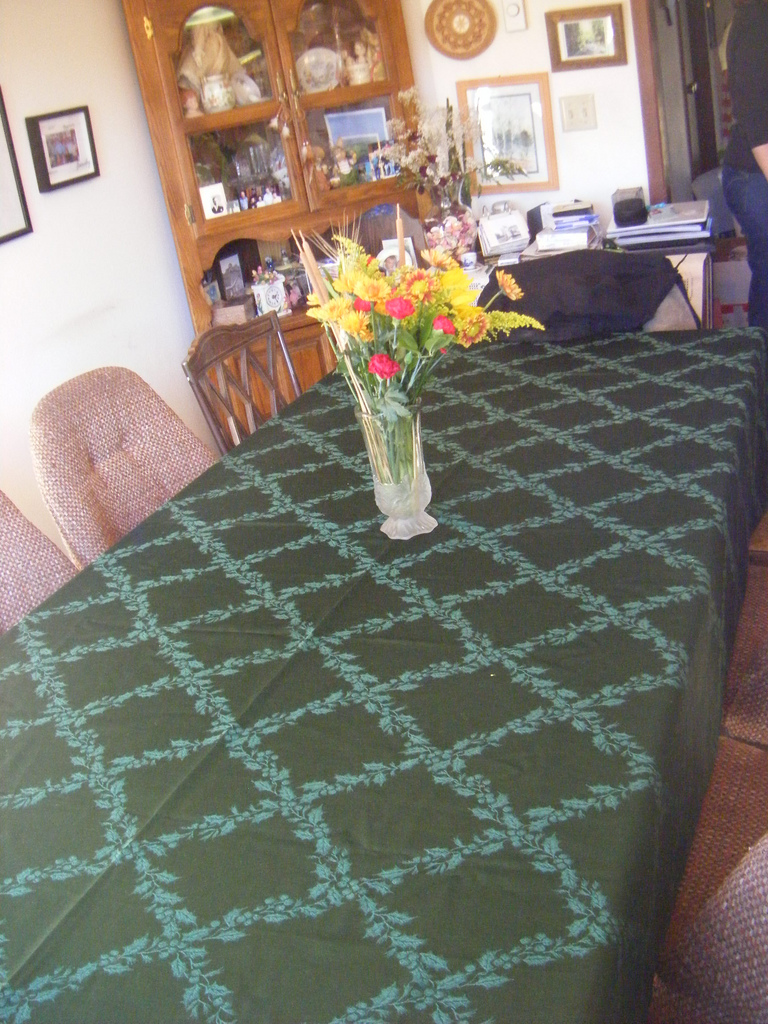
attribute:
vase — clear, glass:
[346, 401, 459, 555]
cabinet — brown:
[122, 2, 450, 378]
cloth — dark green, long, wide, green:
[0, 326, 750, 1023]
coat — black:
[479, 250, 685, 334]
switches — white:
[554, 87, 609, 137]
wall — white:
[0, 3, 623, 500]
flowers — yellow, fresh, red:
[287, 232, 493, 413]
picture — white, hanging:
[21, 98, 109, 214]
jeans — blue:
[712, 173, 767, 317]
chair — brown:
[163, 309, 317, 452]